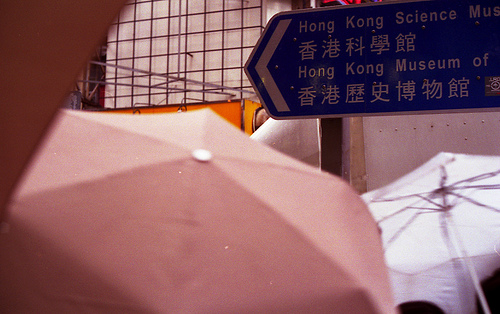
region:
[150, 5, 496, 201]
a street sign on a wal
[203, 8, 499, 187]
a sign on a wall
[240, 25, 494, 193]
a blue and white street sign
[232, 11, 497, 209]
a blue and white sign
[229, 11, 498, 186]
a blue street sign on a wall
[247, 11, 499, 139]
a blue street sign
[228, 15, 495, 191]
a blue and white sign on the wall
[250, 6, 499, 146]
a blue and white street sign on the wall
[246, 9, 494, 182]
a blue sign with white writing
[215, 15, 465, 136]
white lettering on a blue sign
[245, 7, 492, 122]
Located in Hong Kong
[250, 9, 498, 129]
Arrow sign points to museum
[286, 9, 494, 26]
Sign says Hong Kong Science museum.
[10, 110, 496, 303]
People carry umbrellas over their heads.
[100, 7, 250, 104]
Window is barred.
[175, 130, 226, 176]
Umbrella has white cap.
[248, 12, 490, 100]
Blue arrow sign with directions.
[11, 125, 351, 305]
Brown umbrella in front.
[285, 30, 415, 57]
Chinese characters on sign.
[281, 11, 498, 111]
Foreign language and English translation.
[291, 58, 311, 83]
the white letter H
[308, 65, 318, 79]
the white letter O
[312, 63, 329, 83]
the white letter N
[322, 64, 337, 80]
the white letter g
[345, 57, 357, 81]
the white letter K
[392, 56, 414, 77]
the white letter M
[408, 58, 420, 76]
the white letter U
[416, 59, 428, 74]
the white letter s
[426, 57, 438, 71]
the white letter e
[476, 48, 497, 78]
the white letter f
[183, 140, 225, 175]
tip of the umbrella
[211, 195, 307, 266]
pink umbrella that is open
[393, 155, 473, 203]
white umbrella next to pink one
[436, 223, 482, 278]
silver handle of the umbrella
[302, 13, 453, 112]
blue and white sign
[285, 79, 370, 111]
Japanese letters on sign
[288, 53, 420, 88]
English words on the sign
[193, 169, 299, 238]
top part of an umbrella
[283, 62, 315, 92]
the letter H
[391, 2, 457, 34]
the word "science"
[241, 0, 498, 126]
The sign is white and blue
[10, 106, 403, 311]
The umbrella is the color white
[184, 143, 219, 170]
A button on top of the umbrella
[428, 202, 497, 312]
The handle on the umbrella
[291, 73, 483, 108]
The writing is of Asian decent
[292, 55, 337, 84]
The word says "Hong" in white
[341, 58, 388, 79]
The word "Kong" is written in white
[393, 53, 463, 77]
The word "Museum" is the color white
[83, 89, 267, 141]
The lower half of the wall is orange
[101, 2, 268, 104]
The top part of the wall is textured and white